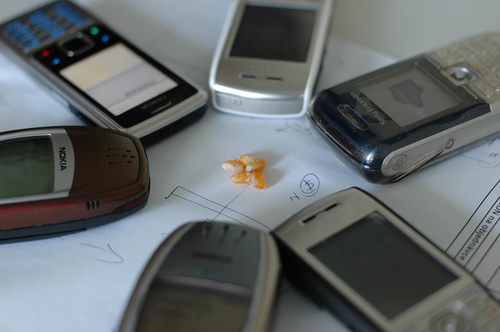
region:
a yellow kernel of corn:
[244, 154, 269, 174]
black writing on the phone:
[54, 141, 69, 177]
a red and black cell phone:
[0, 122, 156, 247]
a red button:
[31, 43, 56, 60]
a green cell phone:
[86, 20, 104, 36]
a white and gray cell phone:
[203, 0, 339, 125]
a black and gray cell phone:
[265, 182, 499, 329]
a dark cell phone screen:
[225, 2, 319, 66]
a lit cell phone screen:
[333, 55, 478, 140]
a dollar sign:
[298, 163, 323, 200]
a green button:
[88, 20, 103, 37]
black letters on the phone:
[54, 138, 71, 175]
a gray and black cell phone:
[268, 182, 497, 329]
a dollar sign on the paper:
[296, 165, 322, 201]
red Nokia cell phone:
[20, 118, 170, 268]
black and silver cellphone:
[324, 53, 498, 173]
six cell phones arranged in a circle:
[17, 20, 456, 306]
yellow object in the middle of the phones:
[212, 145, 299, 207]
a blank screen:
[307, 207, 448, 322]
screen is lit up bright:
[62, 37, 166, 119]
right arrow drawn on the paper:
[61, 228, 158, 292]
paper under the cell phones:
[90, 21, 460, 301]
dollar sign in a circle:
[295, 170, 357, 215]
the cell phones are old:
[45, 41, 486, 285]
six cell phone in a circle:
[52, 26, 464, 306]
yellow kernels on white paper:
[224, 140, 274, 198]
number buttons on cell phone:
[447, 42, 494, 65]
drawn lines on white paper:
[159, 179, 215, 216]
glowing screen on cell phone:
[71, 39, 167, 114]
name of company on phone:
[52, 140, 72, 182]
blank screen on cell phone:
[297, 206, 467, 319]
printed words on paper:
[457, 214, 492, 254]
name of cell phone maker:
[346, 84, 394, 133]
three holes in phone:
[76, 196, 109, 216]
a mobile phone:
[12, 5, 196, 126]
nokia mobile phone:
[7, 125, 142, 232]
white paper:
[22, 263, 130, 321]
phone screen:
[78, 60, 157, 105]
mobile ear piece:
[299, 202, 356, 219]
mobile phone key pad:
[8, 10, 108, 48]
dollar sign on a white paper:
[290, 170, 326, 200]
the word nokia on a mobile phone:
[55, 143, 77, 178]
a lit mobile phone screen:
[65, 55, 207, 121]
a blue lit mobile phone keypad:
[6, 5, 92, 55]